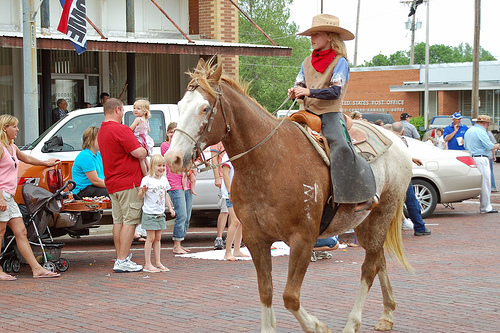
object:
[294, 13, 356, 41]
cowboy hat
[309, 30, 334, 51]
head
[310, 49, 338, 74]
bandana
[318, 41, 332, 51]
neck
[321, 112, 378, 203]
chap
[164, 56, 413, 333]
horse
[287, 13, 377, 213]
girl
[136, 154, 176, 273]
young girl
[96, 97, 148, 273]
man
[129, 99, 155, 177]
child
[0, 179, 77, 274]
stroller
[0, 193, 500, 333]
ground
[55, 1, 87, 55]
flag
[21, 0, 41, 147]
pole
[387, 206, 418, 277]
blond hair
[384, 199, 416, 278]
horse tail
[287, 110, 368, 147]
saddle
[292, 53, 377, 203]
cowboy outfit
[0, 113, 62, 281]
woman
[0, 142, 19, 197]
tank top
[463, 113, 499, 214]
man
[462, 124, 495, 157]
shirt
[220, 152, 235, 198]
shirt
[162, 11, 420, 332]
parade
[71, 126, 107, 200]
woman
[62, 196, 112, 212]
truck bed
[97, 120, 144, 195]
shirt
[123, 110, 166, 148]
window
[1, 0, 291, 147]
building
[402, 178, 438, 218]
tire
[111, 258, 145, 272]
tennis shoe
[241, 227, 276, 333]
leg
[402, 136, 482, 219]
car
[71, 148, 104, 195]
top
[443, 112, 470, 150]
man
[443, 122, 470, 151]
blue shirt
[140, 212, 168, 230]
skirt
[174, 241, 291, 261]
blanket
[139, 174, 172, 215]
shirt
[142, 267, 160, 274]
flip flops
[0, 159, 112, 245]
orange truck